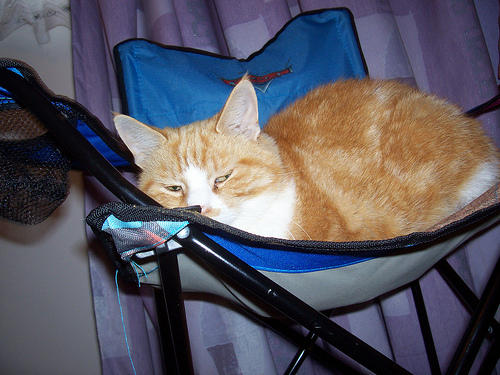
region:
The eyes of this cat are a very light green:
[164, 158, 244, 205]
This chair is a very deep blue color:
[165, 40, 206, 93]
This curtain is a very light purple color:
[431, 38, 452, 70]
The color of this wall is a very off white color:
[16, 287, 35, 335]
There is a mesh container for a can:
[12, 69, 71, 231]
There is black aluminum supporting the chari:
[270, 316, 351, 359]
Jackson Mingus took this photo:
[98, 47, 426, 360]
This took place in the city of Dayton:
[120, 42, 389, 353]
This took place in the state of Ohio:
[148, 58, 410, 335]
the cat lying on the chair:
[112, 78, 498, 248]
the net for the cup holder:
[1, 102, 69, 222]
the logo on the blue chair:
[226, 63, 291, 91]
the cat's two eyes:
[155, 169, 237, 191]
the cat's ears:
[111, 76, 260, 164]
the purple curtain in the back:
[385, 6, 497, 78]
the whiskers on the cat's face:
[232, 172, 312, 242]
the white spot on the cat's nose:
[187, 175, 207, 205]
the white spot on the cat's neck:
[245, 198, 290, 223]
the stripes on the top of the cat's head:
[170, 128, 213, 160]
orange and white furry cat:
[201, 146, 392, 267]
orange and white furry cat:
[201, 108, 415, 220]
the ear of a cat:
[211, 70, 265, 138]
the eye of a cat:
[213, 162, 239, 189]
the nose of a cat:
[181, 198, 213, 229]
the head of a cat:
[106, 69, 276, 223]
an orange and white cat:
[107, 66, 497, 243]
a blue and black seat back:
[111, 5, 371, 132]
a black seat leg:
[148, 247, 210, 373]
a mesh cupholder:
[0, 93, 88, 227]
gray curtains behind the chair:
[66, 0, 499, 374]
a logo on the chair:
[206, 50, 302, 96]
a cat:
[199, 151, 365, 233]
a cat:
[218, 167, 403, 334]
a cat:
[271, 154, 392, 299]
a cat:
[228, 117, 346, 321]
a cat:
[208, 107, 293, 232]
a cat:
[158, 34, 303, 319]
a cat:
[173, 83, 416, 363]